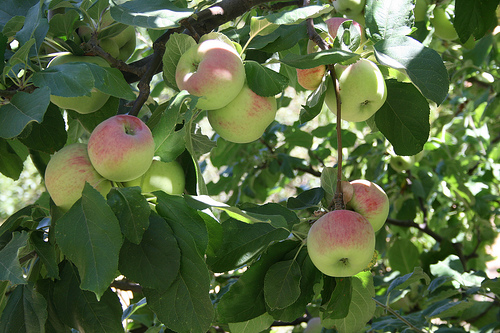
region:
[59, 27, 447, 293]
apples on a tree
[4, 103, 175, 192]
the apples are red and green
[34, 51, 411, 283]
these apples are not ripe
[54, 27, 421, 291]
this picture is showing 10 apples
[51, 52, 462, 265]
these apples look fresh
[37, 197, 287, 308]
leaves on an apple tree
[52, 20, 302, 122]
a tree branch with apples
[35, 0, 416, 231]
an apple tree branch with lots of apples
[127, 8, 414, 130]
the sun is shining on the apples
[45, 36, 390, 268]
the apples are colorful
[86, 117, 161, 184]
A ripe apple on a tree.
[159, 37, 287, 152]
Two apples opposite each other.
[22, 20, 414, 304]
Several apples growing in a cluster on the tree.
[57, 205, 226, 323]
Large apple tree leaves.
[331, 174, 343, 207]
The stem of an apple.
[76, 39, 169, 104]
A t-shaped apple tree branch.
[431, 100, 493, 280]
Extensive foliage in the background.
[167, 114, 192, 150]
A damaged tree leaf.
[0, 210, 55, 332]
Several drooping tree leaves.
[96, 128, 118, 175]
The green and red portions of the apple meet in the center.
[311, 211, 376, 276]
green and purple fruit on branch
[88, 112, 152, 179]
green and purple fruit on branch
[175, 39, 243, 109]
green and purple fruit on branch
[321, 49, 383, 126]
green and purple fruit on branch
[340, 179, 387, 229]
green and purple fruit on branch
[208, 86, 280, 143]
green and purple fruit on branch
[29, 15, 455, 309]
tree branches with leaves and fruits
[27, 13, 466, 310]
leaves casting shadows on tree and fruits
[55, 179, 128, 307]
partially eaten tree leaf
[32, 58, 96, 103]
green tree leaf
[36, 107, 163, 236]
apples grow two by two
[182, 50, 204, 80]
parts of blossom that remain on apple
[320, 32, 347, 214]
apple tree branch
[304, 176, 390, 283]
apple skin is pink and lighter green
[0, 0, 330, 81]
a thicker bough on tree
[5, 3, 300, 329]
many green leaves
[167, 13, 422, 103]
sun shines on the fruit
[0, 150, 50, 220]
vegetation past the tree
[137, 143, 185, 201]
no red shows on this apple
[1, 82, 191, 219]
apples growing in a shaded area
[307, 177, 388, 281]
Unripe apples on a branch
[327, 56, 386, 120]
Green apple on a branch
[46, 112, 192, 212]
Bunch of apples on a branch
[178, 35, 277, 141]
Two apples on a branch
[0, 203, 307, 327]
Bunch of leaves on branches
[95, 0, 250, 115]
Dark branch on tree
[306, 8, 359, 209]
Thin branch carrying apples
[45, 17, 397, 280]
Unripe apples on a tree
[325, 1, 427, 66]
Sun's reflection on leaves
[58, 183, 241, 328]
Large green leaves on branches